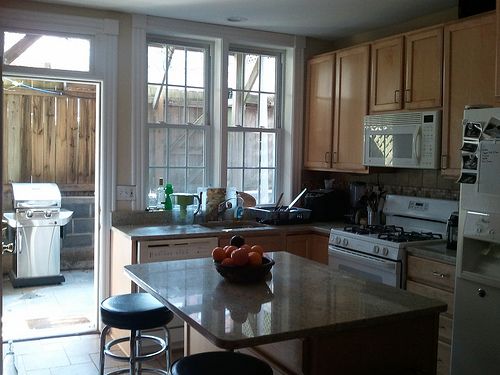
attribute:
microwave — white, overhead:
[355, 108, 442, 171]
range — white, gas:
[325, 192, 460, 291]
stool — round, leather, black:
[97, 291, 172, 374]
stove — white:
[326, 194, 459, 288]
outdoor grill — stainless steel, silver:
[3, 180, 76, 287]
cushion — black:
[98, 289, 174, 329]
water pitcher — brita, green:
[172, 189, 201, 228]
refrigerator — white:
[446, 104, 500, 374]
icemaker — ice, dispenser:
[463, 210, 499, 275]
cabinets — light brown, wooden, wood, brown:
[300, 14, 499, 179]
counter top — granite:
[108, 207, 348, 241]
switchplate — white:
[113, 183, 140, 205]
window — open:
[140, 26, 294, 214]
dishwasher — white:
[133, 234, 224, 295]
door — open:
[2, 76, 99, 328]